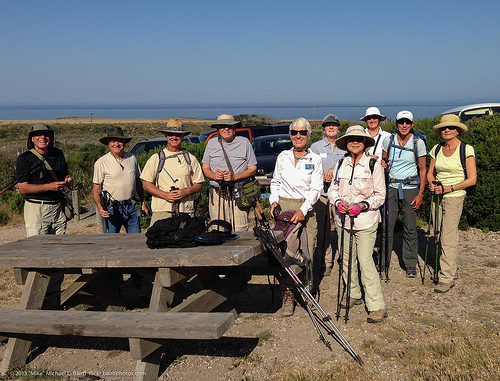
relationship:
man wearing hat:
[14, 121, 76, 239] [27, 122, 56, 133]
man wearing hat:
[138, 118, 203, 233] [157, 117, 191, 136]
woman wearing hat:
[325, 124, 388, 321] [332, 124, 375, 141]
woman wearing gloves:
[325, 124, 388, 321] [334, 200, 362, 217]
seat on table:
[1, 306, 237, 344] [1, 233, 282, 380]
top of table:
[3, 232, 285, 265] [1, 233, 282, 380]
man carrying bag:
[201, 113, 261, 230] [234, 176, 264, 210]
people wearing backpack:
[423, 110, 479, 295] [458, 141, 476, 196]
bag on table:
[145, 212, 240, 249] [1, 233, 282, 380]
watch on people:
[446, 182, 456, 193] [423, 110, 479, 295]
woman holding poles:
[325, 124, 388, 321] [333, 206, 354, 324]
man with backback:
[138, 118, 203, 233] [159, 147, 193, 174]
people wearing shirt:
[423, 110, 479, 295] [428, 142, 476, 198]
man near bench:
[14, 121, 76, 239] [2, 307, 235, 380]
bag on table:
[145, 212, 205, 247] [1, 233, 282, 380]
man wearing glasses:
[138, 118, 203, 233] [165, 131, 186, 138]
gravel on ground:
[276, 342, 303, 360] [2, 220, 498, 379]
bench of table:
[2, 307, 235, 380] [1, 233, 282, 380]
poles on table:
[250, 224, 363, 369] [1, 233, 282, 380]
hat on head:
[332, 124, 375, 141] [331, 126, 375, 158]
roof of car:
[138, 134, 199, 143] [132, 135, 198, 155]